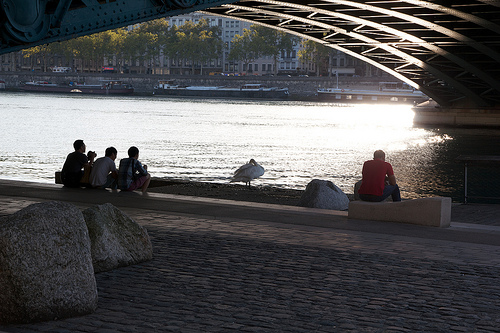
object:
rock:
[82, 202, 153, 272]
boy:
[61, 139, 97, 188]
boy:
[88, 147, 119, 190]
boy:
[117, 146, 151, 193]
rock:
[1, 199, 98, 320]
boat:
[153, 79, 289, 98]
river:
[1, 88, 497, 204]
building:
[103, 23, 148, 73]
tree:
[166, 18, 223, 78]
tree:
[250, 24, 292, 74]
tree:
[297, 34, 332, 77]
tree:
[120, 17, 172, 78]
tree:
[88, 32, 127, 72]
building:
[238, 23, 277, 78]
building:
[170, 10, 224, 77]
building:
[276, 29, 303, 76]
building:
[0, 39, 103, 70]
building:
[324, 43, 356, 77]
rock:
[299, 179, 349, 211]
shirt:
[118, 158, 148, 191]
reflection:
[315, 101, 426, 153]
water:
[0, 93, 500, 201]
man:
[358, 149, 402, 202]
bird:
[229, 158, 264, 190]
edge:
[145, 176, 497, 225]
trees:
[22, 42, 57, 71]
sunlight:
[328, 95, 411, 150]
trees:
[67, 35, 92, 71]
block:
[348, 197, 452, 228]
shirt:
[358, 159, 394, 196]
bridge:
[3, 2, 496, 114]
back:
[235, 163, 256, 184]